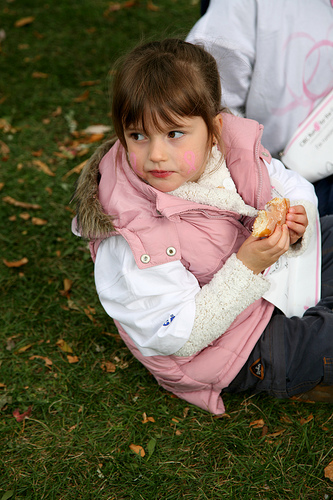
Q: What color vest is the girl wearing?
A: Pink.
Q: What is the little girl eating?
A: Donut.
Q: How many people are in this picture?
A: 2.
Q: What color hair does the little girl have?
A: Brown.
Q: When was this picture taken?
A: Daytime.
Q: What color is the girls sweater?
A: White.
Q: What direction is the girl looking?
A: Left.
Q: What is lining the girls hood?
A: Fur.